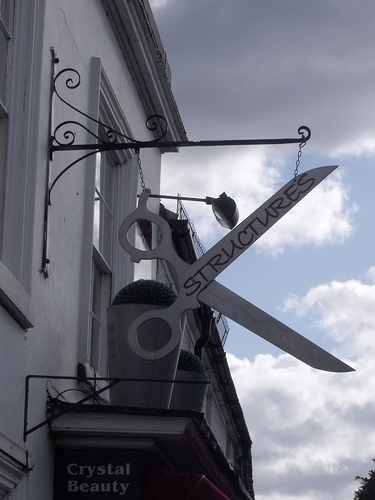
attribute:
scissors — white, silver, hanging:
[117, 164, 359, 375]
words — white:
[66, 460, 132, 498]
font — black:
[185, 173, 315, 295]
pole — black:
[52, 125, 312, 152]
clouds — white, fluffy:
[148, 0, 374, 256]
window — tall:
[80, 55, 116, 400]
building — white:
[1, 1, 192, 499]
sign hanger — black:
[40, 38, 312, 279]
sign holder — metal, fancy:
[25, 364, 212, 440]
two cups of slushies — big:
[105, 278, 212, 415]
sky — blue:
[145, 0, 373, 499]